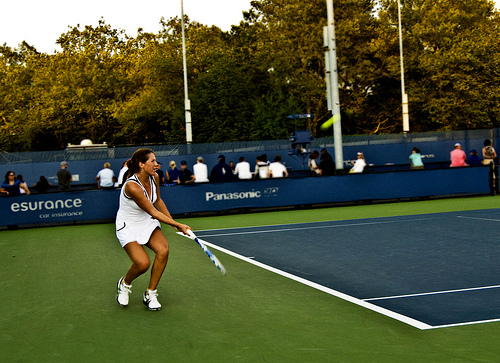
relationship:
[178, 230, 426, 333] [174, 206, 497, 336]
boundary line on tennis court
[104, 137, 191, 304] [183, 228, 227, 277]
person holding racket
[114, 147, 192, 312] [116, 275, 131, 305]
person wearing shoe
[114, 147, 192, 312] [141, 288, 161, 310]
person wearing shoe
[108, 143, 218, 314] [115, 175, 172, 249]
woman wearing outfit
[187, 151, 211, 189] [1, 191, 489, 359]
person standing beside a ten court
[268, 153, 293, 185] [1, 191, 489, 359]
person standing beside a ten court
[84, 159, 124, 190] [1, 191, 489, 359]
person standing beside a ten court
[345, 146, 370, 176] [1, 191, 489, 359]
person standing beside a ten court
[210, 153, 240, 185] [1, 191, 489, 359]
person standing beside a ten court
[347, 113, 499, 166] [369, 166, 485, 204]
wall leaning on fence.